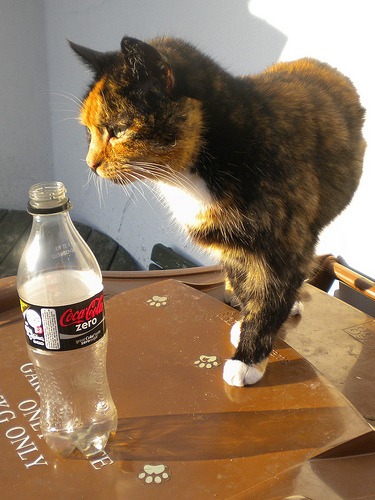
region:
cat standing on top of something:
[60, 32, 373, 462]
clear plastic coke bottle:
[14, 169, 130, 459]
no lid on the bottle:
[20, 183, 67, 210]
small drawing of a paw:
[135, 457, 181, 487]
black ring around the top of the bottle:
[21, 183, 76, 222]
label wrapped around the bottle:
[1, 265, 122, 360]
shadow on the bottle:
[53, 401, 357, 466]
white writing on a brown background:
[0, 355, 132, 487]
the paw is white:
[215, 357, 265, 388]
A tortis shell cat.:
[66, 33, 369, 387]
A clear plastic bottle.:
[14, 179, 117, 459]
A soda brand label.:
[17, 290, 106, 355]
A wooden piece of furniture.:
[0, 254, 373, 499]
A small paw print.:
[136, 460, 172, 488]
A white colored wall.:
[0, 0, 374, 280]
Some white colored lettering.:
[0, 362, 48, 469]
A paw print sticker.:
[191, 352, 221, 370]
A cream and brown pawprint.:
[144, 291, 171, 308]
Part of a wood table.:
[0, 204, 33, 276]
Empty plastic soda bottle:
[13, 178, 121, 458]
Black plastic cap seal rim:
[25, 195, 72, 217]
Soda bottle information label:
[12, 269, 108, 352]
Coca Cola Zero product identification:
[60, 292, 106, 333]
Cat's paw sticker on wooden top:
[129, 460, 175, 486]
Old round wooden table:
[4, 205, 145, 273]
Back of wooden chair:
[141, 241, 202, 269]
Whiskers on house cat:
[79, 159, 205, 207]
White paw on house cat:
[219, 356, 264, 386]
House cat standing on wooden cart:
[56, 33, 367, 385]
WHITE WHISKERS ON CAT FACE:
[150, 168, 177, 184]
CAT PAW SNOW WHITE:
[222, 364, 244, 382]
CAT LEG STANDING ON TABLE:
[234, 245, 296, 393]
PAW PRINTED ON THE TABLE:
[141, 463, 173, 486]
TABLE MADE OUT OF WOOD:
[261, 422, 302, 474]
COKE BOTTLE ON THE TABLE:
[47, 220, 91, 447]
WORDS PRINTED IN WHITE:
[7, 361, 35, 459]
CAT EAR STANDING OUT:
[66, 37, 106, 72]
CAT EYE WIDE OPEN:
[108, 117, 131, 138]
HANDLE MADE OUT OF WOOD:
[340, 272, 367, 287]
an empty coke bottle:
[16, 178, 118, 472]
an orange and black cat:
[67, 18, 371, 387]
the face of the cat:
[72, 39, 208, 185]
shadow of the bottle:
[81, 379, 366, 472]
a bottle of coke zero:
[17, 174, 128, 468]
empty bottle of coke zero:
[18, 177, 113, 470]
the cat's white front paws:
[224, 311, 277, 390]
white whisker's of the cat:
[88, 146, 195, 204]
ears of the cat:
[62, 31, 179, 102]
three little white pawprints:
[134, 280, 219, 491]